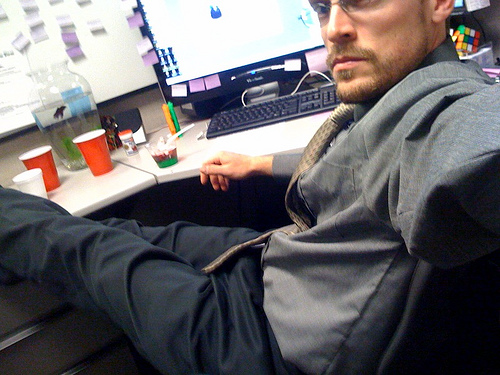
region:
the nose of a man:
[321, 2, 362, 44]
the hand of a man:
[194, 143, 256, 192]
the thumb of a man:
[197, 160, 236, 178]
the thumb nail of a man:
[197, 163, 212, 173]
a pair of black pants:
[1, 182, 301, 373]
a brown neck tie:
[195, 101, 360, 277]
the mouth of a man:
[326, 50, 369, 76]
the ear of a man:
[431, 0, 457, 24]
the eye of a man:
[313, 0, 327, 17]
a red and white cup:
[69, 127, 120, 179]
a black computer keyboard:
[201, 76, 347, 141]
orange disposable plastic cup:
[65, 123, 129, 190]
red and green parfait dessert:
[142, 120, 219, 199]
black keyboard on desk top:
[192, 84, 404, 151]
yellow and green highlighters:
[155, 91, 197, 161]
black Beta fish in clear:
[23, 88, 127, 180]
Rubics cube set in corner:
[450, 8, 488, 72]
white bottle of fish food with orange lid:
[110, 121, 152, 166]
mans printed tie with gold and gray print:
[215, 65, 367, 321]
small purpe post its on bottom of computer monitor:
[155, 62, 261, 119]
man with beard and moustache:
[317, 31, 433, 114]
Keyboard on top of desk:
[202, 77, 340, 137]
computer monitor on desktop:
[131, 0, 326, 85]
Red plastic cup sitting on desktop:
[65, 126, 110, 176]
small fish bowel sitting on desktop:
[32, 96, 106, 171]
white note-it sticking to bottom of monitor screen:
[170, 81, 187, 96]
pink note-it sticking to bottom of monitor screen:
[185, 75, 202, 90]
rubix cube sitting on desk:
[448, 23, 478, 54]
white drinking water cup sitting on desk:
[7, 161, 48, 202]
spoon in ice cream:
[165, 120, 195, 141]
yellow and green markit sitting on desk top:
[159, 101, 180, 133]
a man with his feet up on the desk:
[4, 4, 498, 362]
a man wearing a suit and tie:
[15, 3, 493, 373]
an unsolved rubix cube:
[445, 12, 483, 63]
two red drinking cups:
[17, 127, 134, 183]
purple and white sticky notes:
[135, 15, 234, 112]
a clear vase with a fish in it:
[19, 53, 118, 173]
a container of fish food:
[115, 127, 144, 160]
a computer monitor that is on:
[130, 1, 339, 110]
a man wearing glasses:
[278, 1, 485, 127]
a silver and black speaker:
[106, 105, 155, 157]